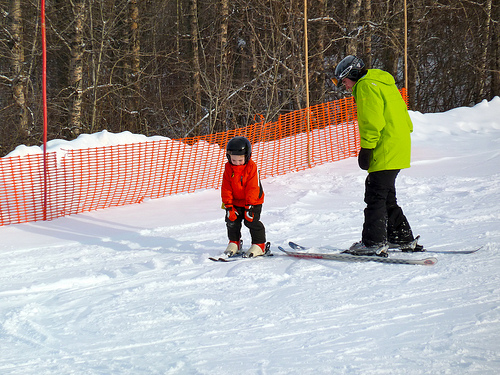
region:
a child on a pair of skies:
[206, 132, 278, 267]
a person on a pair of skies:
[275, 50, 478, 270]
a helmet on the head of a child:
[222, 134, 255, 172]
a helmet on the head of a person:
[321, 50, 369, 100]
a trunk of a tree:
[66, 3, 91, 140]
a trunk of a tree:
[6, 0, 38, 148]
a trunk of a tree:
[123, 8, 150, 123]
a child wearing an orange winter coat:
[206, 135, 279, 266]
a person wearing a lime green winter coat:
[326, 43, 427, 207]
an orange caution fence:
[0, 133, 207, 230]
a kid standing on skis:
[208, 138, 273, 263]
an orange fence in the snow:
[1, 89, 408, 226]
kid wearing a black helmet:
[228, 135, 252, 161]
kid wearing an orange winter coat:
[221, 160, 264, 204]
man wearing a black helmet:
[334, 55, 366, 84]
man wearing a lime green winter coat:
[353, 67, 414, 171]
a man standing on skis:
[278, 54, 484, 265]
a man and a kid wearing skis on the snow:
[211, 57, 483, 265]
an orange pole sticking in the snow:
[40, 0, 48, 220]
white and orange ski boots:
[223, 240, 264, 256]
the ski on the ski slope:
[206, 248, 231, 265]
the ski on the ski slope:
[220, 244, 270, 270]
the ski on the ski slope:
[280, 237, 437, 281]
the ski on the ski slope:
[287, 231, 483, 264]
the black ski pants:
[224, 203, 264, 243]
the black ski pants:
[360, 163, 410, 248]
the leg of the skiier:
[225, 206, 243, 241]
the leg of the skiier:
[245, 203, 268, 245]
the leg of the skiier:
[357, 166, 389, 243]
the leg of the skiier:
[382, 162, 414, 247]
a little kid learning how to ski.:
[210, 129, 275, 265]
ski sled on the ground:
[330, 252, 395, 262]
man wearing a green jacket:
[385, 94, 395, 136]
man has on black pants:
[375, 177, 388, 210]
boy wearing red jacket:
[236, 174, 244, 193]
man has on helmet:
[339, 58, 351, 71]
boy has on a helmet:
[228, 137, 244, 146]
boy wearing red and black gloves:
[224, 209, 235, 221]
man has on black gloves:
[359, 151, 373, 167]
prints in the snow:
[8, 272, 135, 309]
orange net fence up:
[110, 161, 147, 184]